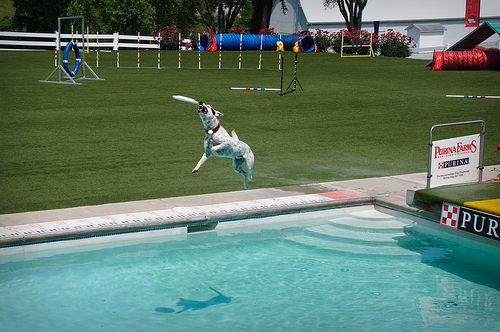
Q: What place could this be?
A: It is a swimming pool.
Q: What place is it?
A: It is a swimming pool.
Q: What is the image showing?
A: It is showing a swimming pool.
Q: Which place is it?
A: It is a swimming pool.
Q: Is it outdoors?
A: Yes, it is outdoors.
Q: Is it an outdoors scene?
A: Yes, it is outdoors.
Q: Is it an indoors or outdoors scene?
A: It is outdoors.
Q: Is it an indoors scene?
A: No, it is outdoors.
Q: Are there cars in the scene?
A: No, there are no cars.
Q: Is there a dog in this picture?
A: Yes, there is a dog.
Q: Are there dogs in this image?
A: Yes, there is a dog.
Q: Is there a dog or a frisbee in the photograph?
A: Yes, there is a dog.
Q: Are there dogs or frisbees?
A: Yes, there is a dog.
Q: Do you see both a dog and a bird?
A: No, there is a dog but no birds.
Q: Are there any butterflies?
A: No, there are no butterflies.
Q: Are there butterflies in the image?
A: No, there are no butterflies.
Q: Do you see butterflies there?
A: No, there are no butterflies.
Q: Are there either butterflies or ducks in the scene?
A: No, there are no butterflies or ducks.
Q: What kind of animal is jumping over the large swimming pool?
A: The animal is a dog.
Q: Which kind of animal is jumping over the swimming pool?
A: The animal is a dog.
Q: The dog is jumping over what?
A: The dog is jumping over the swimming pool.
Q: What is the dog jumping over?
A: The dog is jumping over the swimming pool.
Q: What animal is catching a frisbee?
A: The dog is catching a frisbee.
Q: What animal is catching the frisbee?
A: The dog is catching a frisbee.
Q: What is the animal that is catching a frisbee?
A: The animal is a dog.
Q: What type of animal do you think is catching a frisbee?
A: The animal is a dog.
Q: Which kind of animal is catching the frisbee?
A: The animal is a dog.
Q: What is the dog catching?
A: The dog is catching a frisbee.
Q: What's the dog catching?
A: The dog is catching a frisbee.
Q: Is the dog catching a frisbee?
A: Yes, the dog is catching a frisbee.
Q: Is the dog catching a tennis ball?
A: No, the dog is catching a frisbee.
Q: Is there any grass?
A: Yes, there is grass.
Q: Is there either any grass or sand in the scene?
A: Yes, there is grass.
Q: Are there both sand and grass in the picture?
A: No, there is grass but no sand.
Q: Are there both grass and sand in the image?
A: No, there is grass but no sand.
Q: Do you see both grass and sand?
A: No, there is grass but no sand.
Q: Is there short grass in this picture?
A: Yes, there is short grass.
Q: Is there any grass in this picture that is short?
A: Yes, there is grass that is short.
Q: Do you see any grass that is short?
A: Yes, there is grass that is short.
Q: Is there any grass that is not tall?
A: Yes, there is short grass.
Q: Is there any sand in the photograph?
A: No, there is no sand.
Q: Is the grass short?
A: Yes, the grass is short.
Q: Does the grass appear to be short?
A: Yes, the grass is short.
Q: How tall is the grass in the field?
A: The grass is short.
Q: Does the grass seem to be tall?
A: No, the grass is short.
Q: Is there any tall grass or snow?
A: No, there is grass but it is short.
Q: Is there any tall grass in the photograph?
A: No, there is grass but it is short.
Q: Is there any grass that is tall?
A: No, there is grass but it is short.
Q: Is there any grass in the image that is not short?
A: No, there is grass but it is short.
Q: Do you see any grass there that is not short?
A: No, there is grass but it is short.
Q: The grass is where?
A: The grass is in the field.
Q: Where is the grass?
A: The grass is in the field.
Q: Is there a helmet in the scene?
A: No, there are no helmets.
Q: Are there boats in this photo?
A: No, there are no boats.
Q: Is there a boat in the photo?
A: No, there are no boats.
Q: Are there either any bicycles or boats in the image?
A: No, there are no boats or bicycles.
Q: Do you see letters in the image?
A: Yes, there are letters.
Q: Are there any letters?
A: Yes, there are letters.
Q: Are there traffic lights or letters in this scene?
A: Yes, there are letters.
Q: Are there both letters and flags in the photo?
A: No, there are letters but no flags.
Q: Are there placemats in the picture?
A: No, there are no placemats.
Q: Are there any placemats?
A: No, there are no placemats.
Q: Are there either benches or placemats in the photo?
A: No, there are no placemats or benches.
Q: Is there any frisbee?
A: Yes, there is a frisbee.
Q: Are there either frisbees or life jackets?
A: Yes, there is a frisbee.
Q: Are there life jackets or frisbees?
A: Yes, there is a frisbee.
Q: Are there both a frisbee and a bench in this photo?
A: No, there is a frisbee but no benches.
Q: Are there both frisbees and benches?
A: No, there is a frisbee but no benches.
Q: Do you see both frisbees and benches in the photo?
A: No, there is a frisbee but no benches.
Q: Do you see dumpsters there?
A: No, there are no dumpsters.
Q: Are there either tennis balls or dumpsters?
A: No, there are no dumpsters or tennis balls.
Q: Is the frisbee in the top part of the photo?
A: Yes, the frisbee is in the top of the image.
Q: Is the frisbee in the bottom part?
A: No, the frisbee is in the top of the image.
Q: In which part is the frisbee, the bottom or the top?
A: The frisbee is in the top of the image.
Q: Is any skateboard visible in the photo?
A: No, there are no skateboards.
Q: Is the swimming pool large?
A: Yes, the swimming pool is large.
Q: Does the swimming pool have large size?
A: Yes, the swimming pool is large.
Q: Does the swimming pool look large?
A: Yes, the swimming pool is large.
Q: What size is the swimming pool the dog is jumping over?
A: The swimming pool is large.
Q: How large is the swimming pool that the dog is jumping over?
A: The pool is large.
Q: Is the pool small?
A: No, the pool is large.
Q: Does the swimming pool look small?
A: No, the swimming pool is large.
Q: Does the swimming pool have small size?
A: No, the swimming pool is large.